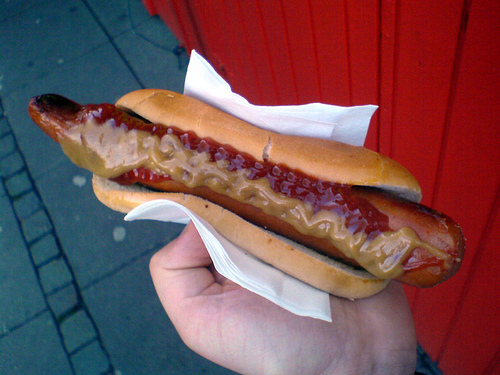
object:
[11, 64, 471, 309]
hot dog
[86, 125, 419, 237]
mustard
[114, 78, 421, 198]
bun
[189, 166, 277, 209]
condiment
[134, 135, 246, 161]
condiment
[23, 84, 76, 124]
burnt area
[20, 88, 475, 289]
meat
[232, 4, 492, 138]
wall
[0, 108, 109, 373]
groundlines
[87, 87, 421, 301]
hotdog bun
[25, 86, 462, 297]
hotdog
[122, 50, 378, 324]
napkin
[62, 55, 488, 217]
hot dog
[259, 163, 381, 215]
ketchup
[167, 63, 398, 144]
napkin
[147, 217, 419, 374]
person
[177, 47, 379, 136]
napkin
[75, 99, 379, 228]
ketchup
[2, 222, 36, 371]
ground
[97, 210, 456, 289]
bottom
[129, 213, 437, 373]
hand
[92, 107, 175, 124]
ketchup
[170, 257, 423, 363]
palm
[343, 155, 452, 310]
end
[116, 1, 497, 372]
person